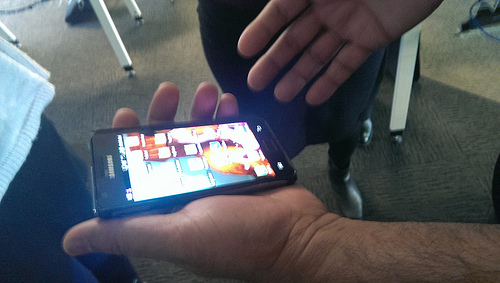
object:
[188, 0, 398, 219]
person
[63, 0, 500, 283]
man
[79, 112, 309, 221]
cell phone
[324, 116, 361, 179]
tights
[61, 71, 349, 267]
hand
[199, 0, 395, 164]
skirt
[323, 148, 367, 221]
shoe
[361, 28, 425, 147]
leg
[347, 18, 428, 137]
object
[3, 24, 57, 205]
sweater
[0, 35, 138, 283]
person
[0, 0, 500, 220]
floor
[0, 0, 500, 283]
room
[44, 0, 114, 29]
shoe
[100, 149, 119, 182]
samsung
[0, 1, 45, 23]
lamp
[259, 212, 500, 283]
arm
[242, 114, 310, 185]
buttons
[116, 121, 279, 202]
screen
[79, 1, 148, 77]
legs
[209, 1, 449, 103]
right hand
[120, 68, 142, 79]
wheels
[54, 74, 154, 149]
shadows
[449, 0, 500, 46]
cord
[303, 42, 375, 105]
fingers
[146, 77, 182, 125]
fingers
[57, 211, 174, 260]
thumb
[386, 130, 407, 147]
wheel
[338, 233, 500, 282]
hair